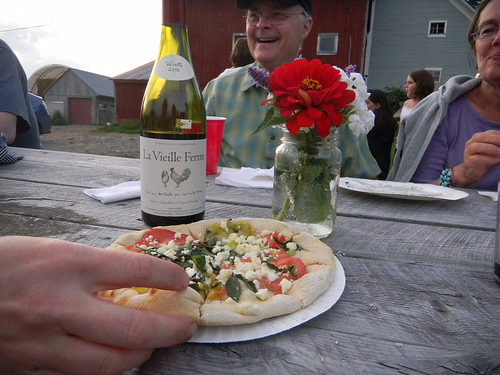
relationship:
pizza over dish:
[66, 217, 337, 327] [175, 247, 349, 348]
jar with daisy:
[264, 121, 344, 242] [257, 50, 359, 138]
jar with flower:
[264, 121, 344, 242] [244, 63, 276, 97]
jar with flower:
[264, 121, 344, 242] [344, 61, 359, 79]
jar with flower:
[264, 121, 344, 242] [341, 70, 378, 140]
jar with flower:
[264, 121, 344, 242] [292, 52, 309, 66]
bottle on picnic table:
[136, 0, 210, 230] [0, 137, 496, 374]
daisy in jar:
[257, 50, 359, 138] [264, 121, 344, 242]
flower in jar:
[341, 70, 378, 140] [264, 121, 344, 242]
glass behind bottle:
[202, 113, 228, 179] [136, 0, 210, 230]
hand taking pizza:
[3, 232, 196, 373] [81, 198, 326, 336]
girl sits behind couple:
[394, 69, 449, 164] [220, 0, 499, 201]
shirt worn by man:
[184, 59, 379, 188] [192, 1, 380, 193]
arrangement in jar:
[250, 60, 373, 133] [276, 127, 341, 238]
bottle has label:
[143, 28, 207, 110] [139, 135, 207, 216]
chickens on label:
[156, 164, 194, 186] [139, 135, 207, 216]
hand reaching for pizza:
[3, 232, 196, 373] [104, 207, 341, 333]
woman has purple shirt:
[392, 13, 498, 183] [411, 96, 498, 186]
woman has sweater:
[433, 13, 498, 168] [378, 70, 465, 165]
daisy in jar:
[257, 50, 359, 138] [253, 113, 379, 245]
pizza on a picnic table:
[60, 211, 394, 362] [0, 137, 496, 374]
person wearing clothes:
[190, 3, 383, 178] [203, 65, 384, 184]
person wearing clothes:
[390, 5, 499, 190] [386, 78, 497, 186]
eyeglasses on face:
[243, 9, 312, 24] [243, 3, 300, 63]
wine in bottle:
[130, 4, 215, 229] [131, 0, 216, 228]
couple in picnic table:
[221, 9, 498, 177] [0, 137, 496, 374]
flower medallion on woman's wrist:
[437, 166, 454, 186] [433, 160, 473, 187]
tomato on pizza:
[268, 257, 307, 279] [66, 217, 337, 327]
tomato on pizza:
[260, 275, 282, 295] [66, 217, 337, 327]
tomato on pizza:
[262, 230, 284, 247] [66, 217, 337, 327]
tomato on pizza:
[126, 228, 197, 253] [66, 217, 337, 327]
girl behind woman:
[384, 40, 490, 210] [441, 4, 499, 111]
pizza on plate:
[66, 217, 337, 327] [337, 174, 471, 206]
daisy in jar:
[263, 73, 366, 150] [264, 121, 344, 242]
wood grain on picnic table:
[373, 221, 495, 318] [353, 180, 498, 374]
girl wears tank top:
[394, 69, 449, 164] [395, 104, 419, 153]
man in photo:
[195, 0, 385, 173] [4, 3, 493, 373]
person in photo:
[390, 5, 499, 190] [4, 3, 493, 373]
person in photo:
[190, 3, 383, 178] [4, 3, 493, 373]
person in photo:
[391, 65, 430, 168] [4, 3, 493, 373]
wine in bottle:
[134, 66, 200, 222] [120, 17, 247, 212]